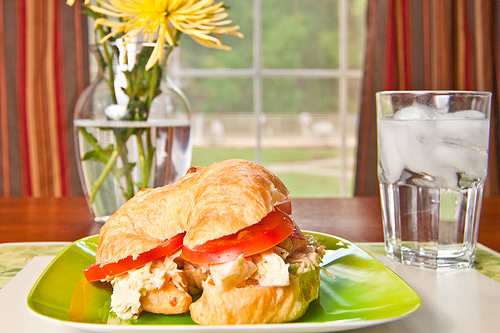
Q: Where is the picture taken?
A: A table.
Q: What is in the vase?
A: Flowers.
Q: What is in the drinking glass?
A: Water.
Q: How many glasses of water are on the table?
A: One.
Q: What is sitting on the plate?
A: Sandwich.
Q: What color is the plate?
A: Green.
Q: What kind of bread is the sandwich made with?
A: Croissant.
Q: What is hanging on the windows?
A: Curtains.